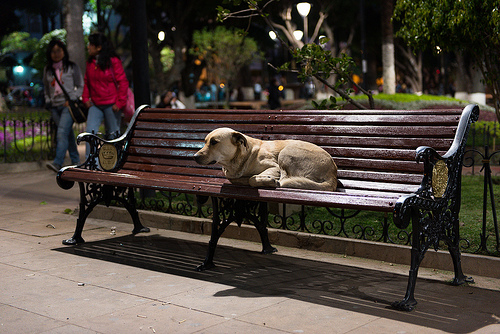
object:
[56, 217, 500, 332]
shadow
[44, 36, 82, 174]
girls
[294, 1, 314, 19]
street light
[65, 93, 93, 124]
bags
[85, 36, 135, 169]
people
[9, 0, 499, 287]
park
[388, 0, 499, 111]
trees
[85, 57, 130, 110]
jacket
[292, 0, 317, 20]
lights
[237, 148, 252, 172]
collar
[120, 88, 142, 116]
bag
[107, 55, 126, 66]
shoulder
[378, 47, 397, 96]
trunks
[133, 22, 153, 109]
pole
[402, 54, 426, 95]
trunk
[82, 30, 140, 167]
girl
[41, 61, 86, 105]
jacket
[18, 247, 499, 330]
sidewalk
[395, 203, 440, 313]
legs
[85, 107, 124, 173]
jeans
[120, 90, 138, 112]
purse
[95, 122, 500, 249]
fence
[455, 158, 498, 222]
area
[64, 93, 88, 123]
bag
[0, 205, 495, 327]
ground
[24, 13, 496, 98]
background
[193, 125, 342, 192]
dog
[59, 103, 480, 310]
bench